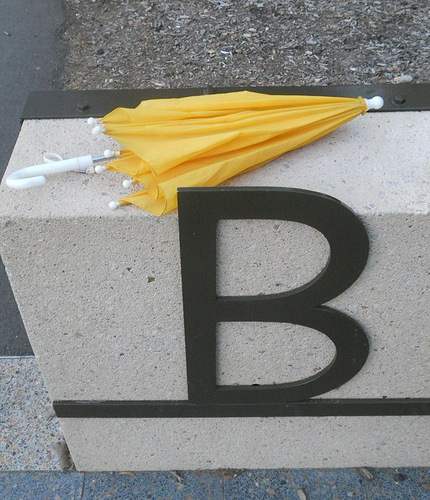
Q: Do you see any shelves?
A: No, there are no shelves.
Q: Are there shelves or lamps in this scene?
A: No, there are no shelves or lamps.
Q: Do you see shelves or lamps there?
A: No, there are no shelves or lamps.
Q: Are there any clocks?
A: No, there are no clocks.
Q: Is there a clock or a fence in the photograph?
A: No, there are no clocks or fences.